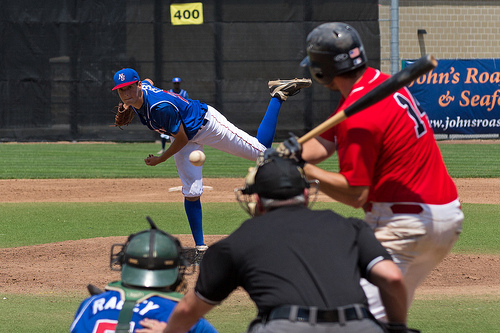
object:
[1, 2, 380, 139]
wall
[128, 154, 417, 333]
umpire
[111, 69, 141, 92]
cap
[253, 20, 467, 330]
player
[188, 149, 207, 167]
ball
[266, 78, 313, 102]
cleat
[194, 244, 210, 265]
cleat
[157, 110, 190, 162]
arm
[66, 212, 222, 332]
catcher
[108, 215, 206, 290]
helmet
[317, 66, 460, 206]
shirt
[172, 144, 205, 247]
leg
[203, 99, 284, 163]
leg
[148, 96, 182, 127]
shoulder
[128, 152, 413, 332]
people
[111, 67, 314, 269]
picher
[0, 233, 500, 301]
mound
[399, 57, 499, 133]
banner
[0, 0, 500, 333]
photo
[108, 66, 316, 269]
pitch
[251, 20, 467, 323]
batter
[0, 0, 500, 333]
stadium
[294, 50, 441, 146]
bat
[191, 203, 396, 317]
man shirt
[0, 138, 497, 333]
baseball field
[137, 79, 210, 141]
blue costume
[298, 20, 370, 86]
helmet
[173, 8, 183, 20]
number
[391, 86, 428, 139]
number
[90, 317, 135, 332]
number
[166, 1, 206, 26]
sign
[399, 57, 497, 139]
sign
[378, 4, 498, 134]
wall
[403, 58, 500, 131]
advertisement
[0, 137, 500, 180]
grass